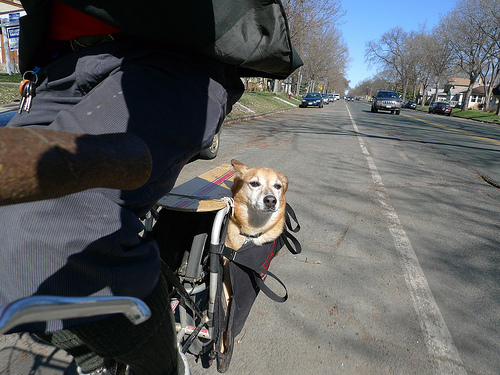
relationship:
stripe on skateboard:
[157, 163, 244, 213] [147, 122, 308, 247]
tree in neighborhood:
[360, 1, 498, 104] [1, 2, 484, 299]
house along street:
[418, 78, 500, 109] [172, 89, 484, 368]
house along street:
[466, 85, 490, 105] [172, 89, 484, 368]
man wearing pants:
[5, 4, 297, 370] [0, 66, 229, 367]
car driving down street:
[371, 90, 401, 115] [338, 137, 448, 333]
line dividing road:
[334, 98, 479, 368] [154, 91, 483, 372]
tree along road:
[435, 1, 499, 112] [154, 91, 483, 372]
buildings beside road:
[415, 62, 487, 118] [437, 117, 495, 181]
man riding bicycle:
[0, 0, 307, 375] [1, 161, 288, 371]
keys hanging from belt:
[13, 65, 42, 121] [14, 31, 226, 81]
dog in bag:
[220, 157, 290, 266] [174, 199, 303, 343]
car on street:
[427, 99, 451, 115] [422, 107, 469, 132]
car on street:
[368, 89, 402, 117] [290, 115, 498, 372]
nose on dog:
[263, 193, 276, 206] [219, 156, 291, 266]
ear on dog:
[225, 155, 249, 176] [207, 144, 317, 306]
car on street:
[371, 90, 401, 115] [172, 89, 484, 368]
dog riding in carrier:
[220, 157, 302, 338] [169, 187, 311, 352]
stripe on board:
[168, 163, 245, 214] [161, 146, 251, 233]